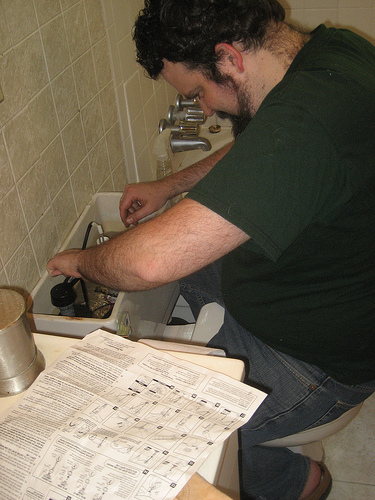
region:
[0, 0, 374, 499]
youngish, bearded dude doing his best to play plumber, along w/ diagram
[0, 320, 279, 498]
extremely complicated diagram w/ many words & pictures for doing fairly simple thing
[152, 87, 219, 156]
complicated bathtub & shower knobs & faucet w/ at least one extra thing that makes no sense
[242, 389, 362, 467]
backward toilet seat being used for fiddling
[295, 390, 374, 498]
marblized tile floor, not marble tho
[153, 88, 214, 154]
Silver colored taps on the wall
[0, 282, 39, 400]
Large silver bowl on white surface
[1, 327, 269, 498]
Large paper with instructions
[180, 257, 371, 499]
Pair of jeans pants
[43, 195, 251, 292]
Hairy arm of a man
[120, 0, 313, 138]
Head with thick black hair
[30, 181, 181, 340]
Man repairing a cistern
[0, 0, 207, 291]
Wall of ceramic tiles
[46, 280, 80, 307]
Round black colored knob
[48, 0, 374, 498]
Man sitting on the toilet seat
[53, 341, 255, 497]
the paer is white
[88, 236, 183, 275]
hair is on the hand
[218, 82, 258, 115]
beard is on the chin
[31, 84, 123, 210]
the wall has tiles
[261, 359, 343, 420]
the jeans are blue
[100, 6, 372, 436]
the guy is seated on the toilet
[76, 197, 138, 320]
the water tank is open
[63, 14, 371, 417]
the guy is fixing the toilet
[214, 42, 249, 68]
the ear is red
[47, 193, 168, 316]
A man is fixing the toilet.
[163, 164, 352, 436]
The man is sitting on the toilet.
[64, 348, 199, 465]
Instructions on the sink.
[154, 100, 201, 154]
Faucets attached to the wall.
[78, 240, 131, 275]
The man arm is hairy.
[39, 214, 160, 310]
Man hand in the water bowl of toilet.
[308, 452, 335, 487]
The man is wearing sandals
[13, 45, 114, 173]
The wall is tiled.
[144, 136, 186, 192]
A soap bottle on the edge of tub.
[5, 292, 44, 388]
A silver container on the sink.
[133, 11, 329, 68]
man has brown hair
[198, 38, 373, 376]
man has green shirt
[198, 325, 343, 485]
man has blue jeans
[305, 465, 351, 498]
man has brown shoes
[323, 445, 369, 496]
white tile on floor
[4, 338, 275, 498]
instruction manual on sink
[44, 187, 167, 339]
white toilet tank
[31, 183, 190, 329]
toilet tank is open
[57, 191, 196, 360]
man working on toilet tank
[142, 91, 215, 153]
silver faucet behind man